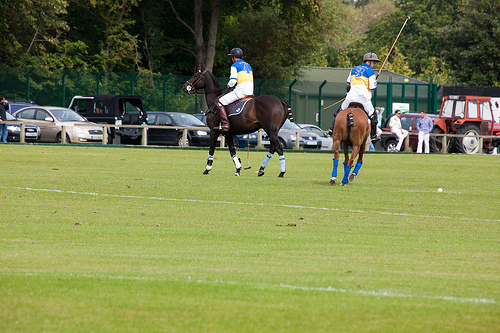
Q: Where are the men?
A: On horses.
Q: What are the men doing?
A: Playing polo.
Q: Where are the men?
A: On the field.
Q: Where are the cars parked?
A: The other side of the field.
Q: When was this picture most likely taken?
A: Summertime.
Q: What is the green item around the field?
A: A fence.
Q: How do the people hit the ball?
A: With the stick.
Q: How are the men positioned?
A: Sitting.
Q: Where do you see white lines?
A: On the field.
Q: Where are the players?
A: On horses.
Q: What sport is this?
A: Polo.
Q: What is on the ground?
A: Grass.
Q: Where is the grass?
A: On the ground.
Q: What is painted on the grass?
A: White lines.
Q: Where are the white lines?
A: Painted on the grass.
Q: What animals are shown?
A: Horses.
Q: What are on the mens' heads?
A: Helmets.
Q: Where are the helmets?
A: On the mens' heads.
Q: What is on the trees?
A: Leaves.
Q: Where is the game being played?
A: On a polo field.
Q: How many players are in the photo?
A: Two.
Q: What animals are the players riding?
A: Horses.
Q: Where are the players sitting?
A: On top of the horses.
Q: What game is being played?
A: Polo.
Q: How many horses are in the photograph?
A: Two.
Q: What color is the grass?
A: Green.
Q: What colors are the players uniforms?
A: Blue, Yellow and White.